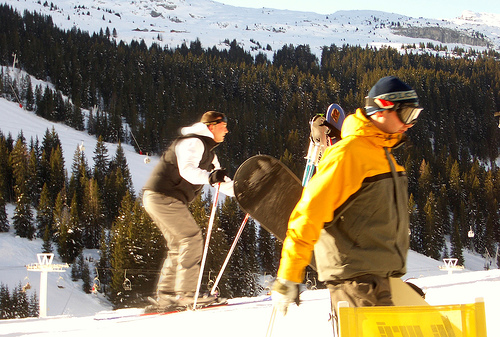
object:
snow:
[76, 143, 86, 150]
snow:
[418, 258, 434, 274]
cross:
[437, 255, 464, 277]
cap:
[363, 75, 420, 115]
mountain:
[139, 24, 383, 49]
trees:
[190, 57, 241, 75]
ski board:
[233, 155, 318, 270]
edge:
[252, 151, 271, 161]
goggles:
[393, 104, 425, 124]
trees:
[304, 58, 339, 77]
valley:
[151, 36, 249, 69]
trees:
[446, 61, 470, 106]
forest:
[62, 47, 123, 85]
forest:
[245, 103, 284, 134]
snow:
[190, 20, 216, 29]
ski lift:
[7, 62, 23, 109]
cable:
[463, 223, 479, 237]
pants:
[143, 191, 205, 293]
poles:
[191, 185, 218, 309]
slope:
[61, 127, 100, 154]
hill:
[3, 67, 63, 103]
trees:
[58, 57, 90, 75]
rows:
[47, 93, 81, 126]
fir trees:
[357, 56, 374, 66]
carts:
[87, 278, 102, 297]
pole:
[40, 272, 48, 323]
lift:
[122, 277, 134, 290]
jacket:
[274, 106, 409, 280]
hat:
[363, 75, 421, 116]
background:
[0, 17, 499, 103]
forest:
[448, 71, 483, 111]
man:
[138, 109, 238, 307]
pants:
[329, 274, 430, 307]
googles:
[396, 106, 423, 124]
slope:
[237, 268, 500, 336]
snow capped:
[162, 26, 185, 36]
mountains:
[378, 22, 489, 49]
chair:
[210, 284, 223, 297]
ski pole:
[193, 185, 220, 308]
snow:
[82, 12, 102, 24]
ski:
[100, 293, 275, 320]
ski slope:
[45, 292, 94, 315]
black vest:
[142, 133, 224, 204]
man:
[270, 74, 465, 336]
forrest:
[66, 41, 95, 71]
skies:
[302, 104, 345, 185]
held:
[270, 276, 302, 317]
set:
[190, 185, 251, 310]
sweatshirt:
[176, 122, 237, 197]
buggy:
[17, 280, 35, 292]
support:
[73, 263, 127, 272]